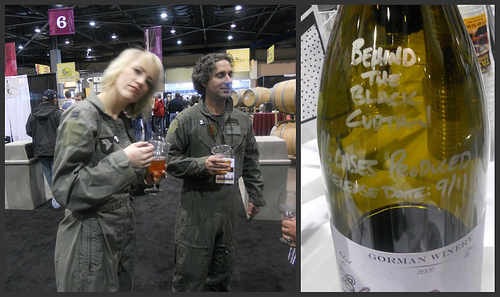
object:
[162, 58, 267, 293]
man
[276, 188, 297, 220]
empty glass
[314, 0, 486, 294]
wine bottle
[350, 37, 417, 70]
silver writing